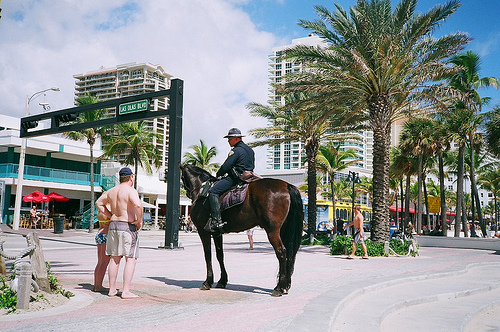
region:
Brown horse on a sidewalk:
[173, 146, 323, 313]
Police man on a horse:
[203, 123, 263, 235]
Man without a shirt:
[98, 165, 153, 285]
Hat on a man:
[116, 163, 141, 187]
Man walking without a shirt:
[343, 200, 378, 262]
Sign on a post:
[107, 96, 157, 123]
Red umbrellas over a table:
[18, 182, 70, 206]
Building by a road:
[61, 58, 196, 220]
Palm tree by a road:
[246, 87, 344, 264]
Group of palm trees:
[389, 113, 499, 243]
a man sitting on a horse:
[179, 83, 319, 290]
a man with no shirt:
[94, 150, 152, 264]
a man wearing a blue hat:
[113, 162, 137, 184]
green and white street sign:
[113, 84, 164, 116]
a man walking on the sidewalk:
[336, 190, 371, 262]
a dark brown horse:
[163, 148, 313, 310]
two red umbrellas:
[11, 182, 73, 207]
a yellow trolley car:
[321, 193, 375, 231]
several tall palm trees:
[379, 83, 484, 232]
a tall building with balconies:
[251, 34, 351, 173]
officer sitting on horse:
[168, 108, 313, 311]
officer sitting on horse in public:
[165, 116, 325, 310]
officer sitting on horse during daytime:
[170, 108, 323, 318]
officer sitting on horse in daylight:
[155, 113, 352, 313]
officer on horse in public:
[162, 105, 327, 310]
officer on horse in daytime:
[135, 111, 352, 322]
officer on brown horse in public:
[165, 108, 334, 312]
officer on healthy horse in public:
[152, 107, 330, 322]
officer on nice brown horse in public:
[147, 114, 329, 309]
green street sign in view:
[98, 88, 163, 131]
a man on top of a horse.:
[174, 121, 318, 298]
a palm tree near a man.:
[281, 0, 498, 250]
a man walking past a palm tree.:
[343, 198, 369, 263]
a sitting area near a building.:
[10, 181, 77, 226]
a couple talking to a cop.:
[93, 164, 148, 299]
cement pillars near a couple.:
[5, 232, 79, 314]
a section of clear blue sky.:
[465, 14, 481, 24]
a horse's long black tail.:
[274, 182, 314, 289]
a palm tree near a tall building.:
[312, 137, 359, 221]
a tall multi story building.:
[254, 26, 401, 171]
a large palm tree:
[304, 2, 475, 276]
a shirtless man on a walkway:
[103, 165, 144, 294]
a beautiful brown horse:
[169, 159, 326, 302]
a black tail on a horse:
[276, 177, 307, 293]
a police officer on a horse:
[200, 119, 267, 235]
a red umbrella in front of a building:
[21, 187, 49, 202]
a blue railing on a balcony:
[2, 153, 121, 186]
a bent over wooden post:
[22, 225, 53, 303]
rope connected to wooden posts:
[0, 239, 45, 274]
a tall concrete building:
[260, 31, 380, 201]